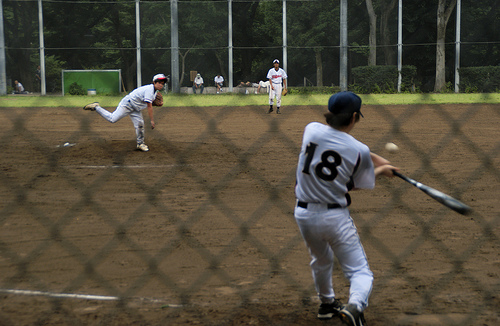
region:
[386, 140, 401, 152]
a small white baseball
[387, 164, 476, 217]
a long black bat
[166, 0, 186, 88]
a long gray pole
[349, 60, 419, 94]
a tall green bush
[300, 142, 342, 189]
the number of the player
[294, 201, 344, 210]
a boy's black belt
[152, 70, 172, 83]
a baseball cap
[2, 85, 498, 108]
a portion of green grass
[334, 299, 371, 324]
the shoe of a boy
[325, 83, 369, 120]
a blue baseball cap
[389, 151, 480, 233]
sturdy black tennis racket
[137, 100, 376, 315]
a man is swinging his bat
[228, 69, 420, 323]
a man is swinging his bat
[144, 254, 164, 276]
Small patch of dirt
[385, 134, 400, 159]
White baseball thrown by the pitcher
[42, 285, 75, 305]
Small part of the white line on baseball field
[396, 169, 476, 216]
Black baseball bat used by batter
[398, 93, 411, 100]
Small patch of green grass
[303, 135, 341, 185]
Number of baseball player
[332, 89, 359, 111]
Blue cap of the batter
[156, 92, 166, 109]
Catching mitt by pitcher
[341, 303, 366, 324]
Right black shoe of batter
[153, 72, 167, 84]
White and orange cap of pitcher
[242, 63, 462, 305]
baseball player swinging his bat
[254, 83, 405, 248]
shirt with the number eighteen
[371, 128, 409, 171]
white baseball flying through the air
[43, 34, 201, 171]
pitcher with his leg in the air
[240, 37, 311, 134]
baseball player standing in the field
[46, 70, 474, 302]
dirt baseball field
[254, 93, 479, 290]
baseball player in a white uniform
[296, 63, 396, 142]
baseball player wearing a blue hat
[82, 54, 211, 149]
baseball player wearing a white hat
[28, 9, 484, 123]
tall fence around field